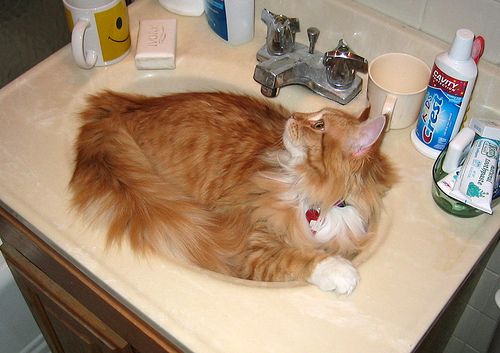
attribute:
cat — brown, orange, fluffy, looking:
[87, 78, 373, 264]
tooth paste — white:
[428, 24, 486, 128]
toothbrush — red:
[473, 34, 493, 67]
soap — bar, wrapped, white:
[129, 17, 170, 62]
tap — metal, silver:
[253, 44, 319, 96]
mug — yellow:
[49, 0, 138, 66]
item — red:
[307, 208, 326, 227]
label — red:
[425, 71, 468, 126]